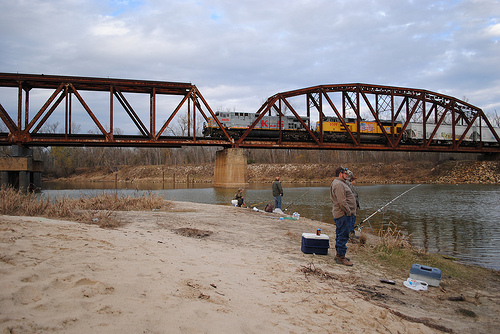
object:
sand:
[0, 201, 500, 333]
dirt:
[0, 200, 500, 333]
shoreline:
[163, 196, 406, 240]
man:
[270, 176, 282, 210]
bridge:
[0, 72, 500, 154]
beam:
[0, 71, 191, 89]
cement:
[222, 160, 227, 168]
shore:
[194, 201, 500, 333]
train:
[200, 111, 500, 146]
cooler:
[300, 232, 332, 255]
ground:
[0, 201, 499, 334]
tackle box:
[406, 263, 440, 287]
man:
[330, 165, 362, 266]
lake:
[29, 182, 498, 272]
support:
[212, 145, 248, 190]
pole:
[361, 183, 422, 224]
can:
[315, 227, 323, 236]